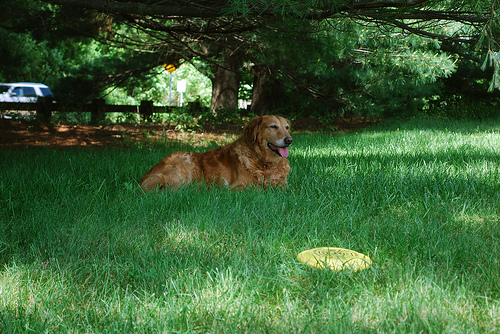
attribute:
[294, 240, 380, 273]
frisbee — yellow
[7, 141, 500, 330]
grass — green, long, bright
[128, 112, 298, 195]
dog — brown, panting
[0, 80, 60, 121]
car — white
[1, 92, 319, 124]
fence — wooden, short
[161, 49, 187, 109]
sign — obscured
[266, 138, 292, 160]
mouth — open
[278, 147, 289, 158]
tongue — pink